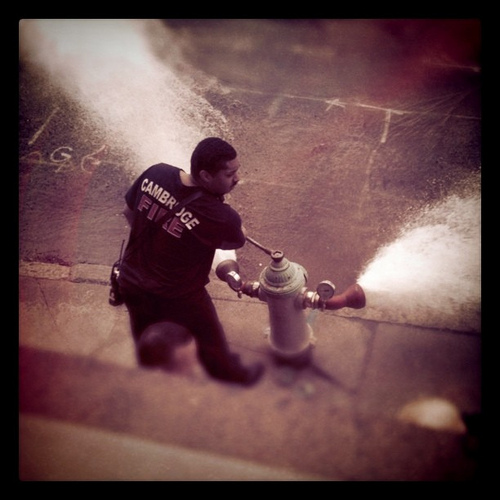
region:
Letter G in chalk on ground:
[44, 135, 76, 181]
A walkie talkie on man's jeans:
[108, 238, 128, 309]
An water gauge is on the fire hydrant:
[316, 280, 336, 314]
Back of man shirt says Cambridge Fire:
[132, 175, 199, 246]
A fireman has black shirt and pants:
[108, 133, 254, 381]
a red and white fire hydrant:
[255, 250, 320, 371]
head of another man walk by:
[138, 315, 210, 383]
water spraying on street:
[366, 247, 477, 314]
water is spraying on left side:
[72, 43, 170, 134]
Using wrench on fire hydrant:
[248, 233, 285, 268]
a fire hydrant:
[246, 250, 361, 374]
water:
[365, 260, 430, 300]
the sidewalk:
[22, 278, 114, 359]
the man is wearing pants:
[187, 309, 234, 370]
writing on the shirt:
[139, 178, 198, 241]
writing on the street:
[26, 128, 109, 178]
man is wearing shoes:
[237, 355, 265, 380]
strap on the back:
[180, 195, 196, 209]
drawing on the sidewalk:
[364, 128, 392, 162]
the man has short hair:
[196, 143, 226, 170]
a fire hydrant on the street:
[261, 246, 363, 382]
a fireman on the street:
[111, 145, 367, 394]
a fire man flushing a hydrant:
[95, 123, 375, 393]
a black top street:
[64, 81, 470, 235]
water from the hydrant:
[160, 83, 284, 290]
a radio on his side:
[102, 251, 144, 314]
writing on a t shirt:
[130, 179, 199, 249]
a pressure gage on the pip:
[312, 263, 394, 340]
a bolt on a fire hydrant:
[262, 242, 284, 269]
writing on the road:
[46, 77, 194, 199]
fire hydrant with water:
[217, 233, 350, 390]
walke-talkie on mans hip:
[102, 236, 144, 318]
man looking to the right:
[178, 132, 270, 202]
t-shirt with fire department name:
[125, 160, 211, 267]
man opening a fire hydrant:
[108, 117, 274, 404]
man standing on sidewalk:
[108, 125, 277, 400]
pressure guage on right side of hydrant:
[315, 279, 340, 308]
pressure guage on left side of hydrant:
[227, 268, 249, 305]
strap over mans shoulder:
[121, 175, 218, 285]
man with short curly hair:
[179, 139, 256, 213]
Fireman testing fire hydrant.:
[77, 99, 394, 391]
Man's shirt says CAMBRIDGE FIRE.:
[123, 173, 224, 248]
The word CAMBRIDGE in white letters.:
[140, 164, 214, 236]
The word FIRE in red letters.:
[131, 193, 191, 242]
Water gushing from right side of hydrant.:
[315, 215, 487, 341]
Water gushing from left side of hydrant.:
[95, 104, 242, 261]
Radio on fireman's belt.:
[95, 228, 130, 309]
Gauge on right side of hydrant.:
[303, 270, 343, 315]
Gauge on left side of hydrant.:
[222, 261, 259, 306]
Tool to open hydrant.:
[238, 219, 294, 264]